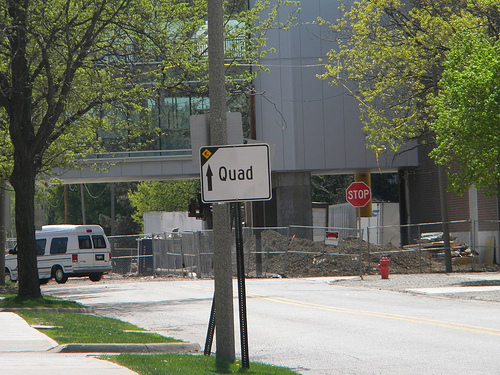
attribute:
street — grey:
[39, 274, 498, 372]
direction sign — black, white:
[197, 142, 272, 373]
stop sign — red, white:
[345, 180, 374, 279]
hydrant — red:
[373, 248, 392, 282]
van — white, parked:
[2, 222, 117, 290]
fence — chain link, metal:
[97, 218, 497, 275]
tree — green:
[1, 1, 308, 298]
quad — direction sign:
[217, 163, 255, 183]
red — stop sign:
[351, 182, 368, 192]